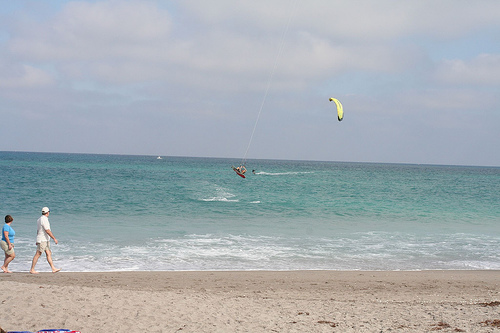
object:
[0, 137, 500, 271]
ocean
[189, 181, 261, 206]
wave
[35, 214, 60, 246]
shirt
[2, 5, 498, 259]
distance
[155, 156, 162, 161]
boat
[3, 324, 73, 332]
towel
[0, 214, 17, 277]
woman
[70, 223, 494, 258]
wave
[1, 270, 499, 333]
beach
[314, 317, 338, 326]
footprints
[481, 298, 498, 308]
footprints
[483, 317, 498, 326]
footprints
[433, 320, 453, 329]
footprints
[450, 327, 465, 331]
footprints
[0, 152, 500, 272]
water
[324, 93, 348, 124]
kite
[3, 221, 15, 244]
shirt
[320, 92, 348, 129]
sail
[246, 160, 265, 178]
man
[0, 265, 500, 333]
sand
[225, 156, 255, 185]
surfer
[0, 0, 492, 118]
sky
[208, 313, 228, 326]
footprints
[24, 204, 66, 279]
man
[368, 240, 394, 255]
waves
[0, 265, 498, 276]
edge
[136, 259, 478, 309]
line